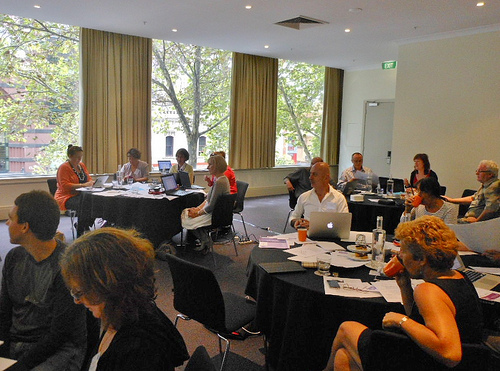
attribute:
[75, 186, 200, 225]
table cloth — black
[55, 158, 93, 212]
cardigan — orange 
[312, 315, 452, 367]
legs — crossed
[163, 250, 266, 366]
empty chair — black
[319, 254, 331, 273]
clear cup — small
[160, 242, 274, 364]
chair — silver 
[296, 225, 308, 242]
cup — orange 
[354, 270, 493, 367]
dress — black 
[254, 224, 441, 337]
tablecloth — black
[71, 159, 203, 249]
tablecloth — black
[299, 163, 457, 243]
tablecloth — black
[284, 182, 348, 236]
shirt — white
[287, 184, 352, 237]
shirt — white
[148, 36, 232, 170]
window — large 